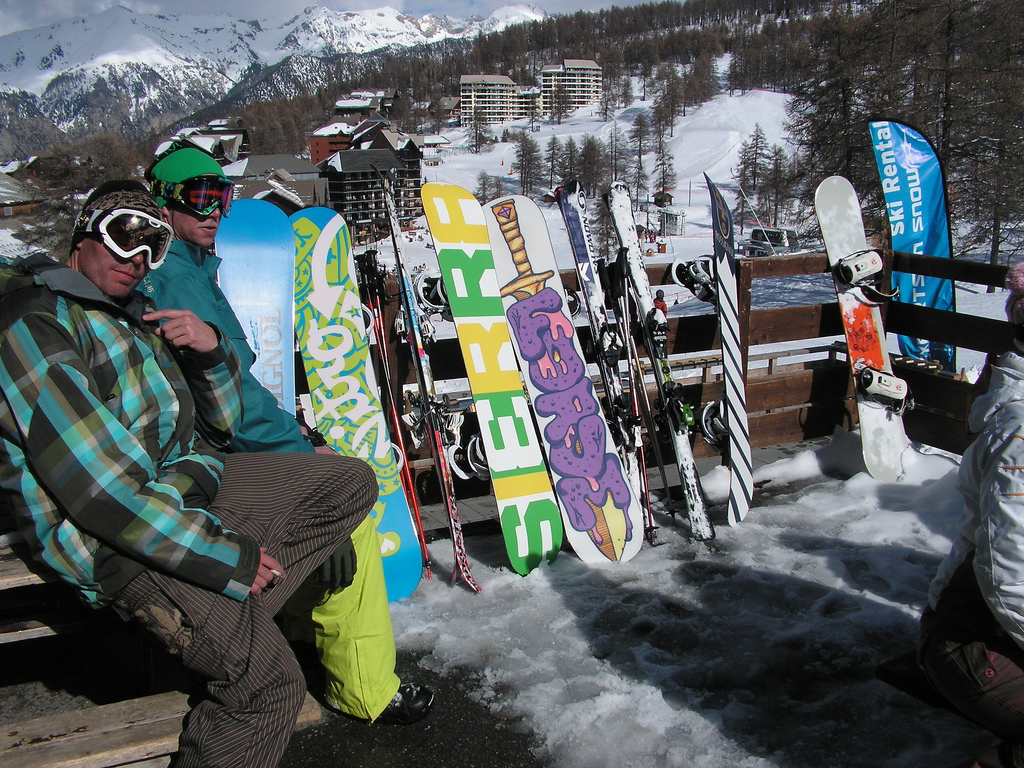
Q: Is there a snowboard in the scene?
A: Yes, there is a snowboard.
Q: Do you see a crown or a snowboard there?
A: Yes, there is a snowboard.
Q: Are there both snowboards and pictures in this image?
A: No, there is a snowboard but no pictures.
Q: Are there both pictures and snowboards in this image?
A: No, there is a snowboard but no pictures.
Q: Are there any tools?
A: No, there are no tools.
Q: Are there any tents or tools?
A: No, there are no tools or tents.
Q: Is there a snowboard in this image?
A: Yes, there is a snowboard.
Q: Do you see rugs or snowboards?
A: Yes, there is a snowboard.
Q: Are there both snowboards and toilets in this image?
A: No, there is a snowboard but no toilets.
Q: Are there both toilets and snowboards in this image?
A: No, there is a snowboard but no toilets.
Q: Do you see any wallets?
A: No, there are no wallets.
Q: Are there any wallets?
A: No, there are no wallets.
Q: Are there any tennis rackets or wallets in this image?
A: No, there are no wallets or tennis rackets.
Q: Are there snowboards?
A: Yes, there is a snowboard.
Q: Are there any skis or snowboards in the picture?
A: Yes, there is a snowboard.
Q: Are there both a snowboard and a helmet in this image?
A: No, there is a snowboard but no helmets.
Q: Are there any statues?
A: No, there are no statues.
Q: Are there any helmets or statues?
A: No, there are no statues or helmets.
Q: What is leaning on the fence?
A: The snowboard is leaning on the fence.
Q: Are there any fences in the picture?
A: Yes, there is a fence.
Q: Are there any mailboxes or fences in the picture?
A: Yes, there is a fence.